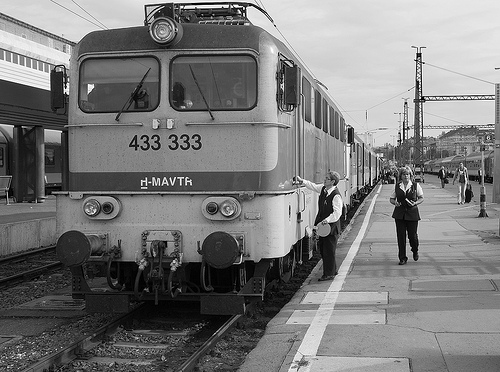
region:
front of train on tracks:
[50, 29, 281, 279]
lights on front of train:
[202, 191, 246, 219]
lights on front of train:
[78, 188, 112, 220]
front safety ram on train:
[194, 226, 239, 270]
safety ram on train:
[55, 229, 90, 260]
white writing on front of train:
[135, 171, 197, 193]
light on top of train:
[155, 13, 170, 41]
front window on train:
[167, 49, 267, 113]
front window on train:
[77, 46, 162, 124]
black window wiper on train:
[105, 68, 156, 116]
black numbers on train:
[132, 128, 232, 156]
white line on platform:
[292, 180, 395, 363]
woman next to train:
[306, 159, 357, 294]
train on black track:
[24, 312, 251, 369]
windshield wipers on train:
[125, 58, 232, 112]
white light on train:
[142, 15, 202, 60]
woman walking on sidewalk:
[387, 168, 439, 277]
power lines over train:
[349, 71, 415, 143]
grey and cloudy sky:
[300, 5, 410, 90]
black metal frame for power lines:
[405, 63, 494, 157]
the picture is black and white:
[30, 2, 490, 357]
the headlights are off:
[47, 172, 259, 224]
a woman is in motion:
[367, 155, 445, 277]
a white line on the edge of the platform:
[287, 215, 369, 363]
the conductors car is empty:
[37, 44, 280, 141]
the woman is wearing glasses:
[305, 165, 355, 189]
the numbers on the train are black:
[103, 119, 219, 166]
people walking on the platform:
[427, 145, 480, 213]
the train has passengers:
[244, 30, 404, 289]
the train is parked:
[65, 29, 409, 316]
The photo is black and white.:
[43, 25, 425, 361]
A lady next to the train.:
[305, 161, 355, 261]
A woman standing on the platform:
[391, 152, 421, 257]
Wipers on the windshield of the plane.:
[111, 65, 216, 120]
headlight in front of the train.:
[76, 187, 236, 222]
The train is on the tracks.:
[2, 121, 278, 363]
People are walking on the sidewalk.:
[423, 149, 499, 211]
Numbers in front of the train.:
[122, 124, 209, 156]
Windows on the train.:
[307, 109, 364, 136]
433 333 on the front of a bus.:
[130, 134, 202, 152]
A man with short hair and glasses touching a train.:
[291, 171, 341, 281]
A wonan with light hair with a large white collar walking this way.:
[391, 165, 426, 264]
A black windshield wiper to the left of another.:
[113, 67, 153, 122]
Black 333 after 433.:
[166, 132, 202, 149]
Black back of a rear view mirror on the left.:
[48, 65, 69, 115]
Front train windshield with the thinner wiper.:
[171, 52, 261, 112]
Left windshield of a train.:
[76, 54, 162, 115]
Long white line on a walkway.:
[276, 182, 383, 369]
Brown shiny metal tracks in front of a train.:
[21, 307, 243, 371]